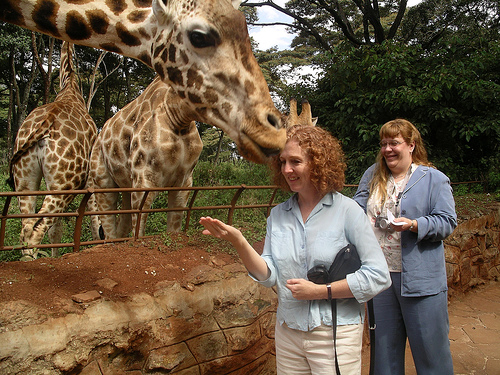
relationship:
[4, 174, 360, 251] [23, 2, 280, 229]
fence below giraffe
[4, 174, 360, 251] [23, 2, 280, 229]
fence under giraffe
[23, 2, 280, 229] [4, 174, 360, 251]
giraffe behind fence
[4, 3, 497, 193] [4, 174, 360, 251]
trees behind fence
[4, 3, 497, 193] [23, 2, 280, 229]
trees behind giraffe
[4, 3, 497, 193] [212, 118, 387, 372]
trees behind woman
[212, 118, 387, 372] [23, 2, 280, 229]
woman near giraffe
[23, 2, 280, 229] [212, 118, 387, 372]
giraffe near woman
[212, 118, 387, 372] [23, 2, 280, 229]
woman close to giraffe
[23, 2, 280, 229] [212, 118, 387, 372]
giraffe close to woman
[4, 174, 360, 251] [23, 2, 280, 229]
fence near giraffe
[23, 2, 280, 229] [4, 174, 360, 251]
giraffe near fence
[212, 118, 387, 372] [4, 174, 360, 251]
woman near fence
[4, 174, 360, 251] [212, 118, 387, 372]
fence near woman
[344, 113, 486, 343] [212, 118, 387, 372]
woman behind woman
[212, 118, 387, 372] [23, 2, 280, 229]
woman beside giraffe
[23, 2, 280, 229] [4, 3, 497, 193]
giraffe beside trees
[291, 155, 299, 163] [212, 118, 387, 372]
eye of woman